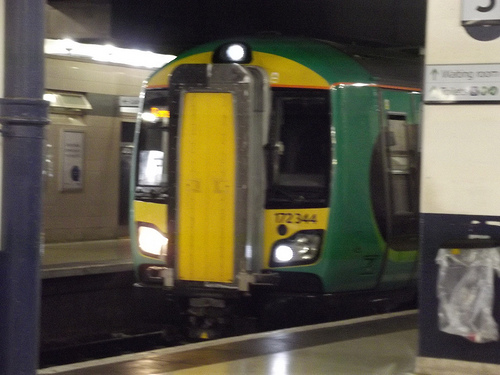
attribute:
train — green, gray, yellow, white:
[125, 27, 420, 343]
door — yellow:
[171, 89, 243, 291]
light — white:
[222, 41, 251, 65]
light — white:
[130, 219, 170, 261]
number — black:
[269, 211, 297, 228]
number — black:
[294, 211, 320, 228]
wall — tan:
[41, 40, 161, 293]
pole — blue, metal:
[1, 1, 54, 374]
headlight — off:
[265, 224, 330, 273]